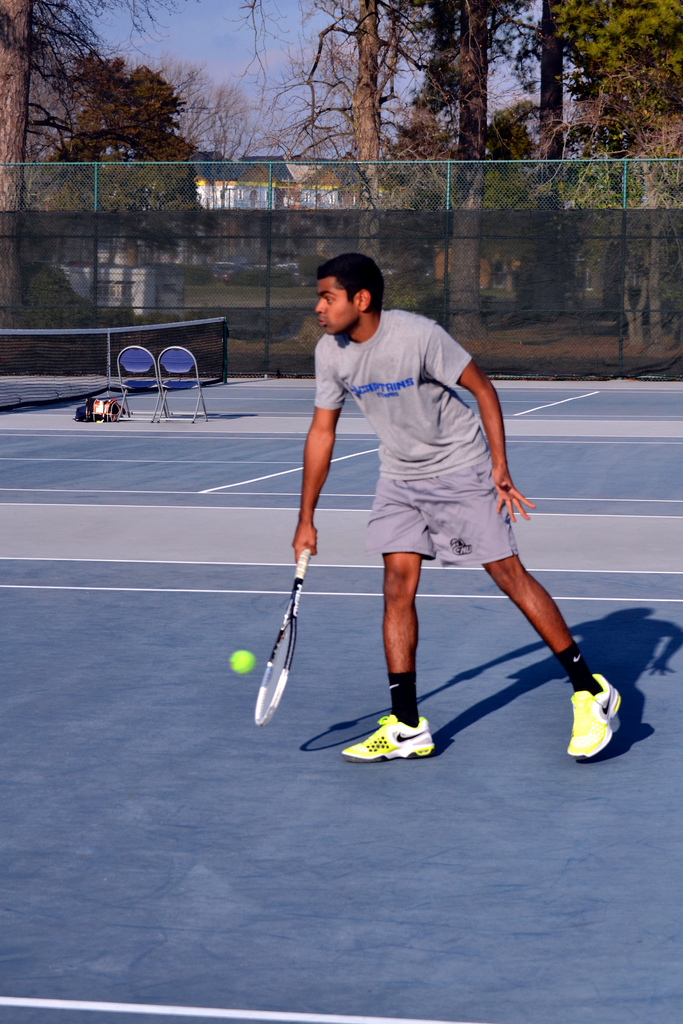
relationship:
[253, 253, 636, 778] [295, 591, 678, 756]
tennis player has shadow